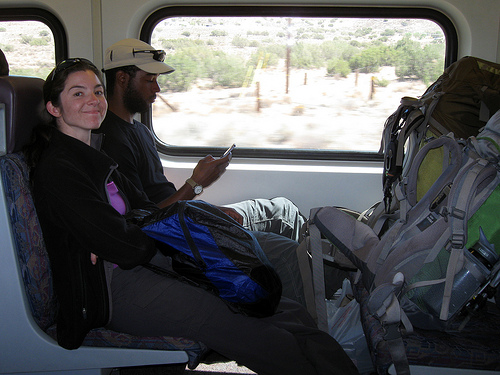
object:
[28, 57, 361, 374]
woman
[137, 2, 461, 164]
window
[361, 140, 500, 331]
backpack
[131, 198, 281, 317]
bag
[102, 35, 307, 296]
man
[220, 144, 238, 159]
phone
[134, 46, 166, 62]
sunglasses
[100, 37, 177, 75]
hat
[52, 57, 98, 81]
sunglasses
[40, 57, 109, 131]
head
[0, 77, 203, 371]
seats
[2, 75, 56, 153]
head rest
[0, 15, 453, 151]
ground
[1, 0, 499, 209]
side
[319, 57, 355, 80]
bushes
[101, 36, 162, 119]
head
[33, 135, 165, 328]
shirt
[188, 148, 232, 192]
hand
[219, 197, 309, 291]
jeans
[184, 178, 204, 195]
watch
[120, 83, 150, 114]
beard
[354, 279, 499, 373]
seat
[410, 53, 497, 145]
backpack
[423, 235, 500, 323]
bottle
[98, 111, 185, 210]
shirt